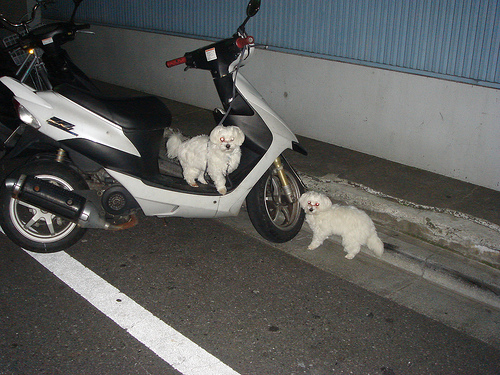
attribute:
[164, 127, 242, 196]
dog — white, small, cute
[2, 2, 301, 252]
bike — parked, white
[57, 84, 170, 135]
seat — black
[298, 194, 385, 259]
dog — white, small, cute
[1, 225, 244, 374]
line — white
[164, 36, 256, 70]
handles — red, small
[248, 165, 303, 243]
tire — black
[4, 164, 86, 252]
tire — black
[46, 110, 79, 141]
label — small